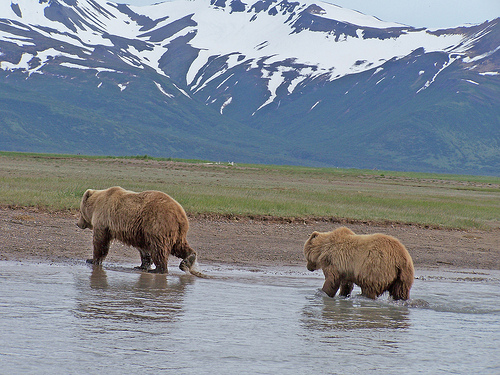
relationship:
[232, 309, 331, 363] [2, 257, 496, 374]
part of water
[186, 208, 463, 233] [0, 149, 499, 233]
edge of grass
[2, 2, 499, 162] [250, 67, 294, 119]
mountain covered in snow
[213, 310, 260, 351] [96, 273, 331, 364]
part of water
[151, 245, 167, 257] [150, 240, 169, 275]
part of leg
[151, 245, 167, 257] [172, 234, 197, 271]
part of leg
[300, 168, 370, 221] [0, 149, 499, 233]
part of grass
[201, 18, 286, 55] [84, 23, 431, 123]
snow covered mountain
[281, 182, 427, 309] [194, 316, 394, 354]
bear walking out water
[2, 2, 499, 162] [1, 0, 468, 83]
mountain covered in snow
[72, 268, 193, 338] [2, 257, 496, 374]
bear reflection on water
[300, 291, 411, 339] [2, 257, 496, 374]
reflection on water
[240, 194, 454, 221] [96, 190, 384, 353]
grass beyond water